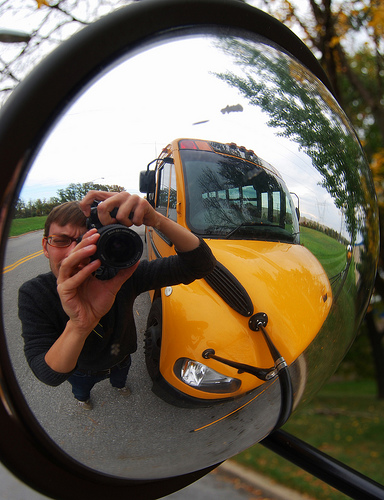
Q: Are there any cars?
A: No, there are no cars.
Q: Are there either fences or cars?
A: No, there are no cars or fences.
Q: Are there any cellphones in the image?
A: No, there are no cellphones.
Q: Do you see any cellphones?
A: No, there are no cellphones.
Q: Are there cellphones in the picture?
A: No, there are no cellphones.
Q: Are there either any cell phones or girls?
A: No, there are no cell phones or girls.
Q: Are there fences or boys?
A: No, there are no fences or boys.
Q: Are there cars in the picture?
A: No, there are no cars.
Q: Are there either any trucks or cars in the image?
A: No, there are no cars or trucks.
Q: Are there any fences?
A: No, there are no fences.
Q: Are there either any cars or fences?
A: No, there are no fences or cars.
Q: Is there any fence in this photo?
A: No, there are no fences.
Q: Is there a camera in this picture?
A: Yes, there is a camera.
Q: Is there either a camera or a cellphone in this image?
A: Yes, there is a camera.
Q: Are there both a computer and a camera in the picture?
A: No, there is a camera but no computers.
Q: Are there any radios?
A: No, there are no radios.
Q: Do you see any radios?
A: No, there are no radios.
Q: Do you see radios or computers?
A: No, there are no radios or computers.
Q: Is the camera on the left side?
A: Yes, the camera is on the left of the image.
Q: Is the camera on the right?
A: No, the camera is on the left of the image.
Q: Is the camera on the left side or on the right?
A: The camera is on the left of the image.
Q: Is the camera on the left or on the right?
A: The camera is on the left of the image.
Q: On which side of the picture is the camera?
A: The camera is on the left of the image.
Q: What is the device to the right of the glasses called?
A: The device is a camera.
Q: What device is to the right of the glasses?
A: The device is a camera.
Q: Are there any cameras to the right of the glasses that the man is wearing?
A: Yes, there is a camera to the right of the glasses.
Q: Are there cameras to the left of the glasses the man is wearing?
A: No, the camera is to the right of the glasses.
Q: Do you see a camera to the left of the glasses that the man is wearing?
A: No, the camera is to the right of the glasses.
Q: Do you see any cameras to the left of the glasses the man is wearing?
A: No, the camera is to the right of the glasses.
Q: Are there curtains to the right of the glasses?
A: No, there is a camera to the right of the glasses.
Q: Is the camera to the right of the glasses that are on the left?
A: Yes, the camera is to the right of the glasses.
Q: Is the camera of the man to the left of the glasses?
A: No, the camera is to the right of the glasses.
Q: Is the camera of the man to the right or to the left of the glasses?
A: The camera is to the right of the glasses.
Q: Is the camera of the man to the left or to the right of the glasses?
A: The camera is to the right of the glasses.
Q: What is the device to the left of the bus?
A: The device is a camera.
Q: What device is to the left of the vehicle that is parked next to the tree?
A: The device is a camera.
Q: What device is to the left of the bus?
A: The device is a camera.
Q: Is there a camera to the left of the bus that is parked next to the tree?
A: Yes, there is a camera to the left of the bus.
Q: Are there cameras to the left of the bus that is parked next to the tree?
A: Yes, there is a camera to the left of the bus.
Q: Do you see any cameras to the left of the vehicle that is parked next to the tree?
A: Yes, there is a camera to the left of the bus.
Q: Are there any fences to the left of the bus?
A: No, there is a camera to the left of the bus.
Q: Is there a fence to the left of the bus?
A: No, there is a camera to the left of the bus.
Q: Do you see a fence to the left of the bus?
A: No, there is a camera to the left of the bus.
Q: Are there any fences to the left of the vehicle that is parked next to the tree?
A: No, there is a camera to the left of the bus.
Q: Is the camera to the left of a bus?
A: Yes, the camera is to the left of a bus.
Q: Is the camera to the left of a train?
A: No, the camera is to the left of a bus.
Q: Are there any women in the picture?
A: No, there are no women.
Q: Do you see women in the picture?
A: No, there are no women.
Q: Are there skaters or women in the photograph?
A: No, there are no women or skaters.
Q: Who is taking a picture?
A: The man is taking a picture.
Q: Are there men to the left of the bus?
A: Yes, there is a man to the left of the bus.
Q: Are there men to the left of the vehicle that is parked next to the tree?
A: Yes, there is a man to the left of the bus.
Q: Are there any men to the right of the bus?
A: No, the man is to the left of the bus.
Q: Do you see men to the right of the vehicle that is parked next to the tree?
A: No, the man is to the left of the bus.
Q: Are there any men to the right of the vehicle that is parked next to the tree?
A: No, the man is to the left of the bus.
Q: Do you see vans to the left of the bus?
A: No, there is a man to the left of the bus.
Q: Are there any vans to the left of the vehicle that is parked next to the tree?
A: No, there is a man to the left of the bus.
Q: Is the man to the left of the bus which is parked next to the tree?
A: Yes, the man is to the left of the bus.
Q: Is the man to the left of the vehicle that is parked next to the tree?
A: Yes, the man is to the left of the bus.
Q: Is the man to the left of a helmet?
A: No, the man is to the left of the bus.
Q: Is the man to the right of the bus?
A: No, the man is to the left of the bus.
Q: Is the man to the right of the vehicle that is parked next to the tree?
A: No, the man is to the left of the bus.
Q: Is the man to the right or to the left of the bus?
A: The man is to the left of the bus.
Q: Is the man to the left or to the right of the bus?
A: The man is to the left of the bus.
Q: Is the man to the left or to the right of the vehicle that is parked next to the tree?
A: The man is to the left of the bus.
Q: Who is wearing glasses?
A: The man is wearing glasses.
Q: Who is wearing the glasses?
A: The man is wearing glasses.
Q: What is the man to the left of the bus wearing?
A: The man is wearing glasses.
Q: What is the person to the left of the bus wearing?
A: The man is wearing glasses.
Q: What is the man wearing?
A: The man is wearing glasses.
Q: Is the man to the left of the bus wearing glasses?
A: Yes, the man is wearing glasses.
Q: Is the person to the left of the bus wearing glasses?
A: Yes, the man is wearing glasses.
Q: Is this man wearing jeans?
A: No, the man is wearing glasses.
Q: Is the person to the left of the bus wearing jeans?
A: No, the man is wearing glasses.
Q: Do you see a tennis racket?
A: No, there are no rackets.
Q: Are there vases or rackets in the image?
A: No, there are no rackets or vases.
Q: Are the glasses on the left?
A: Yes, the glasses are on the left of the image.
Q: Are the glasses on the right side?
A: No, the glasses are on the left of the image.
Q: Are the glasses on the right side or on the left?
A: The glasses are on the left of the image.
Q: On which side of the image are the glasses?
A: The glasses are on the left of the image.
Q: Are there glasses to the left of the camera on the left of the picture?
A: Yes, there are glasses to the left of the camera.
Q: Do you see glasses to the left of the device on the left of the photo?
A: Yes, there are glasses to the left of the camera.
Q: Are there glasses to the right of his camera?
A: No, the glasses are to the left of the camera.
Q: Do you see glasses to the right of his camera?
A: No, the glasses are to the left of the camera.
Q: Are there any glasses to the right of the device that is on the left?
A: No, the glasses are to the left of the camera.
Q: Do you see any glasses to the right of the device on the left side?
A: No, the glasses are to the left of the camera.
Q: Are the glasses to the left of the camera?
A: Yes, the glasses are to the left of the camera.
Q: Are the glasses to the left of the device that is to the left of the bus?
A: Yes, the glasses are to the left of the camera.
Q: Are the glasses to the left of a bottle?
A: No, the glasses are to the left of the camera.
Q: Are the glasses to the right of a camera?
A: No, the glasses are to the left of a camera.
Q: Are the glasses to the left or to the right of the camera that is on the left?
A: The glasses are to the left of the camera.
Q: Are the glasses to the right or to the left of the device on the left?
A: The glasses are to the left of the camera.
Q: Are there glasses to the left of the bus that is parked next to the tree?
A: Yes, there are glasses to the left of the bus.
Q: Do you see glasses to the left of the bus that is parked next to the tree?
A: Yes, there are glasses to the left of the bus.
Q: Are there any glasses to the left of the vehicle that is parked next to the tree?
A: Yes, there are glasses to the left of the bus.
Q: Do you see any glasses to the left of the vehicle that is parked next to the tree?
A: Yes, there are glasses to the left of the bus.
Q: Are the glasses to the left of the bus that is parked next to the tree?
A: Yes, the glasses are to the left of the bus.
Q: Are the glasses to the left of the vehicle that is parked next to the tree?
A: Yes, the glasses are to the left of the bus.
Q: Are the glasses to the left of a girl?
A: No, the glasses are to the left of the bus.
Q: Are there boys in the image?
A: No, there are no boys.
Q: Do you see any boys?
A: No, there are no boys.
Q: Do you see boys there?
A: No, there are no boys.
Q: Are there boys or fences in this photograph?
A: No, there are no boys or fences.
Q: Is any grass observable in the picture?
A: Yes, there is grass.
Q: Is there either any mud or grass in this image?
A: Yes, there is grass.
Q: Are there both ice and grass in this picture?
A: No, there is grass but no ice.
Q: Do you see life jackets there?
A: No, there are no life jackets.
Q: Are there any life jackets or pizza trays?
A: No, there are no life jackets or pizza trays.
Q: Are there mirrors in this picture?
A: Yes, there is a mirror.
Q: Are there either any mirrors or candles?
A: Yes, there is a mirror.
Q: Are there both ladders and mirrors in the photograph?
A: No, there is a mirror but no ladders.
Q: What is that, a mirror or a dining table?
A: That is a mirror.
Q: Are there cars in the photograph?
A: No, there are no cars.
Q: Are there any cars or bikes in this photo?
A: No, there are no cars or bikes.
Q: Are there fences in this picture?
A: No, there are no fences.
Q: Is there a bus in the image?
A: Yes, there is a bus.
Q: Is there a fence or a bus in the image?
A: Yes, there is a bus.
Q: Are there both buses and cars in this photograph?
A: No, there is a bus but no cars.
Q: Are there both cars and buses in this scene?
A: No, there is a bus but no cars.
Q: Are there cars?
A: No, there are no cars.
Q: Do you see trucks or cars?
A: No, there are no cars or trucks.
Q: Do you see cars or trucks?
A: No, there are no cars or trucks.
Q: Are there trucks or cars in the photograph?
A: No, there are no cars or trucks.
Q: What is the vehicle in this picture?
A: The vehicle is a bus.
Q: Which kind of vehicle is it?
A: The vehicle is a bus.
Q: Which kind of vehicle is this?
A: This is a bus.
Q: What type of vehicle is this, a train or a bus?
A: This is a bus.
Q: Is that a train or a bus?
A: That is a bus.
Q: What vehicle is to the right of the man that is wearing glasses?
A: The vehicle is a bus.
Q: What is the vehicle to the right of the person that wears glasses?
A: The vehicle is a bus.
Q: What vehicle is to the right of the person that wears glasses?
A: The vehicle is a bus.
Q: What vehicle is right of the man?
A: The vehicle is a bus.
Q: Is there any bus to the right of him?
A: Yes, there is a bus to the right of the man.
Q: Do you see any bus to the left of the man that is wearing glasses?
A: No, the bus is to the right of the man.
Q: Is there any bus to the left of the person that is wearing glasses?
A: No, the bus is to the right of the man.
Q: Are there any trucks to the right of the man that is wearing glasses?
A: No, there is a bus to the right of the man.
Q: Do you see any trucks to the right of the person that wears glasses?
A: No, there is a bus to the right of the man.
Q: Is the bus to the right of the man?
A: Yes, the bus is to the right of the man.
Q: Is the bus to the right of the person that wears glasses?
A: Yes, the bus is to the right of the man.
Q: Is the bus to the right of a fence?
A: No, the bus is to the right of the man.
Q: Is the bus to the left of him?
A: No, the bus is to the right of the man.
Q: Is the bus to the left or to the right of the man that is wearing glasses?
A: The bus is to the right of the man.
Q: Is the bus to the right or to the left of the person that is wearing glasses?
A: The bus is to the right of the man.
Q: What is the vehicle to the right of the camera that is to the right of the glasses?
A: The vehicle is a bus.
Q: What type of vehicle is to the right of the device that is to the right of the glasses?
A: The vehicle is a bus.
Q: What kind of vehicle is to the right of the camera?
A: The vehicle is a bus.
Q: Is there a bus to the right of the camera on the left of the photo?
A: Yes, there is a bus to the right of the camera.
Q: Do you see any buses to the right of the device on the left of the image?
A: Yes, there is a bus to the right of the camera.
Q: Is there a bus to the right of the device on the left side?
A: Yes, there is a bus to the right of the camera.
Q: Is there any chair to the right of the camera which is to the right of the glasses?
A: No, there is a bus to the right of the camera.